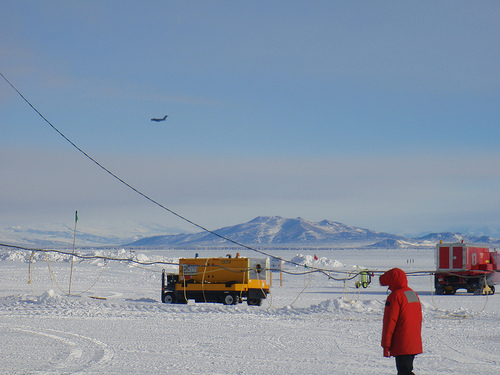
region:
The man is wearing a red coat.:
[376, 266, 424, 373]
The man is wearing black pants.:
[377, 267, 427, 374]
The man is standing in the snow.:
[373, 268, 430, 373]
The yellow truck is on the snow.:
[161, 247, 273, 311]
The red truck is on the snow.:
[429, 231, 498, 296]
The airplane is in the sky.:
[147, 108, 172, 125]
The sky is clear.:
[333, 42, 498, 100]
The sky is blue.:
[286, 110, 384, 151]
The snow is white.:
[113, 333, 209, 374]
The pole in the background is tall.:
[65, 203, 82, 310]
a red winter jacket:
[355, 260, 462, 371]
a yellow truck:
[130, 237, 354, 340]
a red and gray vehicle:
[408, 215, 498, 292]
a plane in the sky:
[131, 80, 195, 139]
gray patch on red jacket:
[407, 288, 421, 312]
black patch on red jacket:
[380, 298, 400, 317]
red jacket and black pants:
[361, 252, 418, 374]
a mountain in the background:
[95, 194, 462, 262]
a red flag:
[302, 245, 339, 299]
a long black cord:
[10, 70, 456, 285]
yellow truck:
[139, 246, 274, 317]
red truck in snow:
[432, 234, 498, 312]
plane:
[132, 103, 180, 134]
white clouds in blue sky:
[60, 23, 116, 59]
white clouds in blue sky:
[252, 53, 292, 100]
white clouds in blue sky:
[354, 82, 401, 124]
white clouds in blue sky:
[287, 158, 323, 190]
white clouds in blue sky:
[358, 174, 390, 209]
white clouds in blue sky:
[352, 169, 383, 196]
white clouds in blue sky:
[51, 32, 86, 62]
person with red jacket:
[355, 263, 429, 369]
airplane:
[142, 99, 173, 138]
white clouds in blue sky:
[66, 37, 99, 79]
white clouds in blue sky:
[301, 39, 353, 69]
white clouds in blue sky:
[403, 10, 450, 44]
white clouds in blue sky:
[317, 86, 385, 143]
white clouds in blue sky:
[260, 148, 328, 190]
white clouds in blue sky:
[352, 107, 437, 164]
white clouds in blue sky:
[34, 71, 72, 107]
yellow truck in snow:
[139, 249, 277, 301]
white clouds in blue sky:
[29, 30, 71, 91]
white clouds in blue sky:
[142, 35, 191, 69]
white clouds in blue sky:
[320, 25, 370, 91]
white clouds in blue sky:
[423, 22, 491, 77]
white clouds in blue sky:
[302, 90, 336, 134]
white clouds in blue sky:
[369, 154, 429, 204]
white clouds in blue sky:
[223, 159, 242, 179]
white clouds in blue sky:
[129, 141, 171, 183]